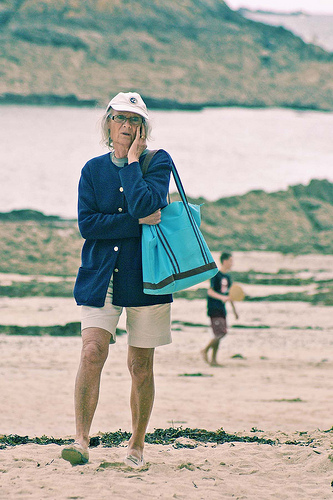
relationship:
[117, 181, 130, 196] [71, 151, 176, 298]
button on sweater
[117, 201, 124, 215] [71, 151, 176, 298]
button on sweater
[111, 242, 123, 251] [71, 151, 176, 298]
button on sweater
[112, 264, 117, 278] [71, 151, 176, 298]
button on sweater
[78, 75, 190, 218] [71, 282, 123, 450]
woman has leg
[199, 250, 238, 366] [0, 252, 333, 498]
boy on beach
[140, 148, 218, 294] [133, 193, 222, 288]
bag has lines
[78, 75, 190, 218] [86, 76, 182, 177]
woman has head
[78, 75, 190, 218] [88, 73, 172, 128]
woman wears hat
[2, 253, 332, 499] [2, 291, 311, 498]
sand on ground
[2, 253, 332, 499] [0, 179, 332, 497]
sand on ground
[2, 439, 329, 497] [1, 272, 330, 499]
sand on ground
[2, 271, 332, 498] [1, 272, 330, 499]
white sand on ground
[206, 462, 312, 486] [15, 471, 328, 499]
sand on ground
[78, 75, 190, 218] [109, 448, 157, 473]
woman wearing shoe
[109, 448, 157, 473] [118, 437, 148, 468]
shoe on left foot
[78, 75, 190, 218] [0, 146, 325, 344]
woman on beach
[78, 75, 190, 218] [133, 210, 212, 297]
woman holding bag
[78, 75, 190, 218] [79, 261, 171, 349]
woman wears short pant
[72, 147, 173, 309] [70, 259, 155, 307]
sweater has pockets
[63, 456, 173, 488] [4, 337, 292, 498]
sand on ground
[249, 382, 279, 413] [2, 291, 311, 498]
sand on ground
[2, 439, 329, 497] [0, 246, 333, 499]
sand on ground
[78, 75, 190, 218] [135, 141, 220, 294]
woman carrying blue tote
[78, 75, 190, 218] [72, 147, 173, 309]
woman in sweater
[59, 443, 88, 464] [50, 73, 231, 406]
shoe of woman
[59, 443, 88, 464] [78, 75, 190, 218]
shoe on woman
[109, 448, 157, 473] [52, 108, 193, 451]
shoe on woman